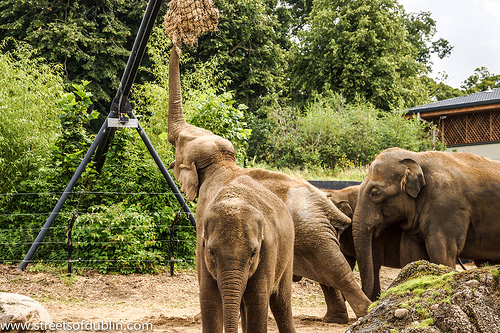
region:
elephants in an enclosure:
[39, 80, 471, 288]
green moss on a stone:
[401, 275, 435, 295]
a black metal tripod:
[69, 104, 163, 271]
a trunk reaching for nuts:
[163, 59, 191, 151]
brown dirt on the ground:
[88, 291, 149, 331]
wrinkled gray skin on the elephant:
[297, 208, 327, 246]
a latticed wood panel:
[449, 118, 488, 141]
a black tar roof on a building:
[444, 94, 480, 105]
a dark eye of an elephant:
[363, 174, 390, 205]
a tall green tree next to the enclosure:
[334, 9, 396, 94]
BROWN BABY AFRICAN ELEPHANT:
[200, 176, 277, 331]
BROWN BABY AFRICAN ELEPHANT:
[354, 146, 498, 276]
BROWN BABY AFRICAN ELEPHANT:
[273, 175, 350, 300]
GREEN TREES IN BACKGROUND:
[13, 24, 439, 255]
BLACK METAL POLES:
[43, 12, 197, 268]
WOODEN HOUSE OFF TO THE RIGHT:
[414, 84, 499, 147]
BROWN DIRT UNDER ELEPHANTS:
[20, 262, 285, 331]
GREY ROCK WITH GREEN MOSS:
[364, 255, 493, 317]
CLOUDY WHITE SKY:
[431, 0, 498, 89]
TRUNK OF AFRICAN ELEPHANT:
[219, 262, 247, 329]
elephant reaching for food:
[162, 40, 332, 206]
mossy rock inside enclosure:
[370, 250, 495, 325]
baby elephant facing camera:
[195, 175, 295, 330]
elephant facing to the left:
[350, 135, 490, 265]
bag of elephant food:
[160, 0, 220, 45]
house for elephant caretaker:
[400, 85, 495, 155]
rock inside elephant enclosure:
[0, 285, 50, 325]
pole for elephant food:
[15, 0, 195, 275]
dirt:
[50, 270, 205, 330]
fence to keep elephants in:
[0, 185, 191, 281]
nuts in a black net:
[162, 4, 221, 44]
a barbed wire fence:
[83, 189, 168, 281]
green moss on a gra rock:
[400, 277, 450, 299]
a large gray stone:
[0, 287, 43, 329]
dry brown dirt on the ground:
[99, 301, 146, 323]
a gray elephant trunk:
[210, 276, 257, 328]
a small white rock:
[391, 302, 414, 319]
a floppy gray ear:
[398, 153, 425, 200]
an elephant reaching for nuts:
[164, 51, 269, 176]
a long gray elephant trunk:
[357, 205, 373, 283]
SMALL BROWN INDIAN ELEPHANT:
[193, 173, 320, 325]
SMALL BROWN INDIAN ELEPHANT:
[360, 149, 490, 246]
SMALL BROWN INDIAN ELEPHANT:
[281, 170, 346, 290]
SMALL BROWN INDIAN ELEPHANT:
[331, 188, 358, 224]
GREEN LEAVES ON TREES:
[18, 12, 418, 239]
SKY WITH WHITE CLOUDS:
[421, 9, 497, 66]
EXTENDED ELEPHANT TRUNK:
[163, 8, 205, 145]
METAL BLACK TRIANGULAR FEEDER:
[27, 15, 215, 264]